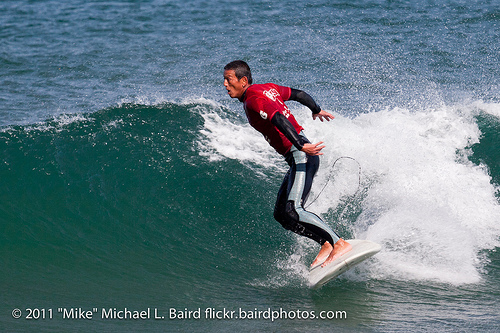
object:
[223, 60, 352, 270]
man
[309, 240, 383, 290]
surf board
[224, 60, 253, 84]
hair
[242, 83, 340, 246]
wet suit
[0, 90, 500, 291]
wave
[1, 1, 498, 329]
ocean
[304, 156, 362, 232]
cord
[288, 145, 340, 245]
stripe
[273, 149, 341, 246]
lightweight pants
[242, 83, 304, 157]
red shirt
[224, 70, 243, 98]
face